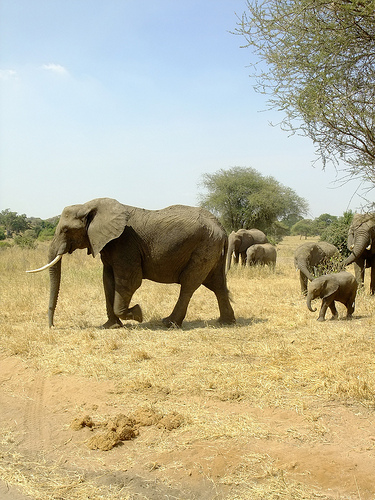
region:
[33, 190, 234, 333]
gray elephant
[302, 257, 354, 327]
baby gray elephant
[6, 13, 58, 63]
white and green ocean waves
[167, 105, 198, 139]
white and green ocean waves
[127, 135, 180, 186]
white and green ocean waves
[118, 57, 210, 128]
white and green ocean waves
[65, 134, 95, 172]
white and green ocean waves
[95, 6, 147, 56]
white and green ocean waves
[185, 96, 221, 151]
white and green ocean waves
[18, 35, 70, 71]
white clouds in blue sky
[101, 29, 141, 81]
white clouds in blue sky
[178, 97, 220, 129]
white clouds in blue sky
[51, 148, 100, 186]
white clouds in blue sky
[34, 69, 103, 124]
white clouds in blue sky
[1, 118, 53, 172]
white clouds in blue sky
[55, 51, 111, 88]
white clouds in blue sky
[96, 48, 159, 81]
white clouds in blue sky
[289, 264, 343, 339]
baby elephant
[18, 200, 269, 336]
elephant walking on the grass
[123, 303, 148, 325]
foot is lifted off the ground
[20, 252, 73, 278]
long white tusk on the side of the trunk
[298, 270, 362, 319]
small baby elephant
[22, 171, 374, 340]
a herd of elephants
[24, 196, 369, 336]
baby elephant walking behind an adult elephant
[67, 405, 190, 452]
pile of dung on the ground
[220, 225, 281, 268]
small elephant standing next to a bigger one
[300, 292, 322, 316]
bottom of the trunk is curled under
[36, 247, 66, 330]
trunk hanging down towards the ground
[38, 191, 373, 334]
Six elephants walking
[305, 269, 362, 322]
Baby elephant to the right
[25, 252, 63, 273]
Front elephant has white tusks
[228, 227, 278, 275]
Mother and baby elephants are to the back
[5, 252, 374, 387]
Grass is a golden color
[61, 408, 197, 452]
Elephant dunn on the ground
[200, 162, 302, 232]
Green bush in the distance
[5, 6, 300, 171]
Blue skies over head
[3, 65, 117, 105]
One very small cloud in the sky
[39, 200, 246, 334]
Elephant color is dark grey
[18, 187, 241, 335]
the elephant is walking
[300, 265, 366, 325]
the elephant is a baby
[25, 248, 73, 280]
elephant tusk is white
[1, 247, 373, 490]
the grass is yellow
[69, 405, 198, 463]
piles of grass on ground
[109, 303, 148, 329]
elephant's foot off ground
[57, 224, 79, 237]
elephant's eye is black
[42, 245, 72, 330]
elephant's trunk pointing down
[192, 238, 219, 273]
brown spots on elephant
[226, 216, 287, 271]
elephants standing next to each other